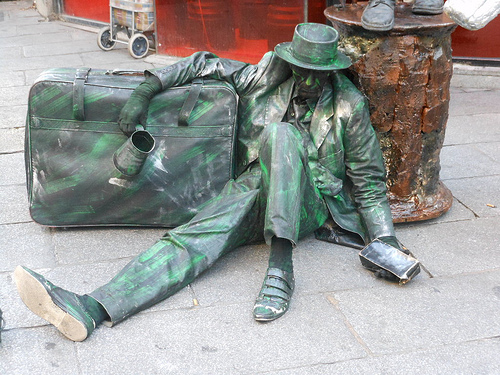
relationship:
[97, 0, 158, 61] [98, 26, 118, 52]
cart has wheel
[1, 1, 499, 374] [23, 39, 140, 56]
sidewalk has square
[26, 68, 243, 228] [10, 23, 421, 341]
suitcase by beggar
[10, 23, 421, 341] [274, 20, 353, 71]
beggar has fedora hat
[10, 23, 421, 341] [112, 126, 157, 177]
beggar has can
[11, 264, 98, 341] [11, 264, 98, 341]
shoe has shoe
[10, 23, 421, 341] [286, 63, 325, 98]
beggar has a face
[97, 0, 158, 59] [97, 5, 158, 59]
cart has lower portion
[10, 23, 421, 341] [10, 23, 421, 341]
beggar of a beggar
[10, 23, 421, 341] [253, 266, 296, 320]
beggar has a shoe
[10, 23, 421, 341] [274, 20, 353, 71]
beggar has a fedora hat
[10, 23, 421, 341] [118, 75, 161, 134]
beggar has a hand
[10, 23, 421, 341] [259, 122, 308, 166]
beggar has a knee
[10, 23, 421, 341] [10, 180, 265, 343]
beggar has a leg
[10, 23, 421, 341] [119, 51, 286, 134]
beggar has an arm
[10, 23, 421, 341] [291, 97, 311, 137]
beggar has a tie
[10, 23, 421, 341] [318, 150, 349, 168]
beggar has a pocket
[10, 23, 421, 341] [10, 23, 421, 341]
beggar dressed as a beggar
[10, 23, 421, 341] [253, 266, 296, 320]
beggar wearing a shoe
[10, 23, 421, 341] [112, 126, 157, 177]
beggar holding can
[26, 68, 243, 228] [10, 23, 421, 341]
suitcase beside beggar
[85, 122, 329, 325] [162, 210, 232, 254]
pants have wrinkles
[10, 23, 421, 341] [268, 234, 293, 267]
beggar has sock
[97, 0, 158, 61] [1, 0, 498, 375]
cart on ground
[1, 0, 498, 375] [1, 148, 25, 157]
ground has crack